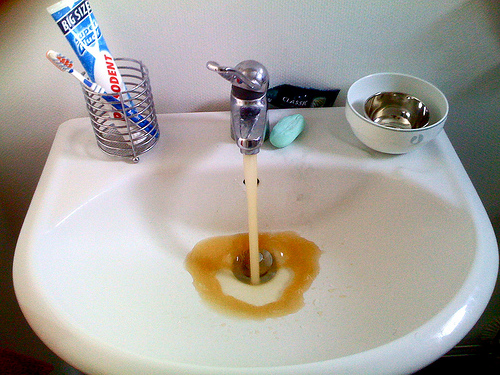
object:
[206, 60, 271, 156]
faucet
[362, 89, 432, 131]
bowl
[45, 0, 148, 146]
tooth paste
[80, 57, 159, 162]
steel holder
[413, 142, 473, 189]
wall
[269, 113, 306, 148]
soap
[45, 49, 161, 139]
toothbrush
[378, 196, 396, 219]
ground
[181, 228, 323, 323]
water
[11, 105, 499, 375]
sink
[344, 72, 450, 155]
bowl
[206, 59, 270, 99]
handle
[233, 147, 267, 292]
water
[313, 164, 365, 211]
ground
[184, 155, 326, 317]
water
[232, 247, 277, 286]
sink drain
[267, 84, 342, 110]
paper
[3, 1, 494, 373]
wall